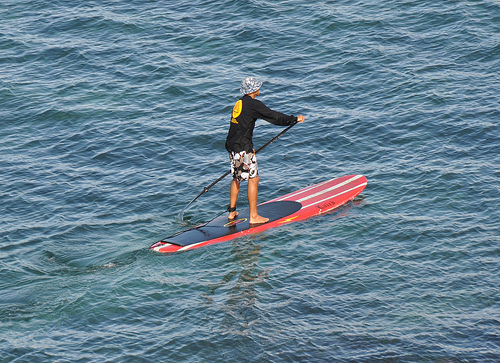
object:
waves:
[141, 47, 194, 102]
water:
[0, 1, 500, 363]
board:
[150, 174, 368, 253]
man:
[224, 75, 305, 223]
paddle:
[180, 118, 301, 211]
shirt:
[224, 95, 298, 154]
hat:
[239, 76, 263, 95]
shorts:
[229, 150, 260, 182]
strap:
[228, 205, 238, 212]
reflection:
[201, 232, 273, 332]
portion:
[384, 29, 446, 79]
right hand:
[297, 114, 306, 123]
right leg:
[247, 152, 270, 224]